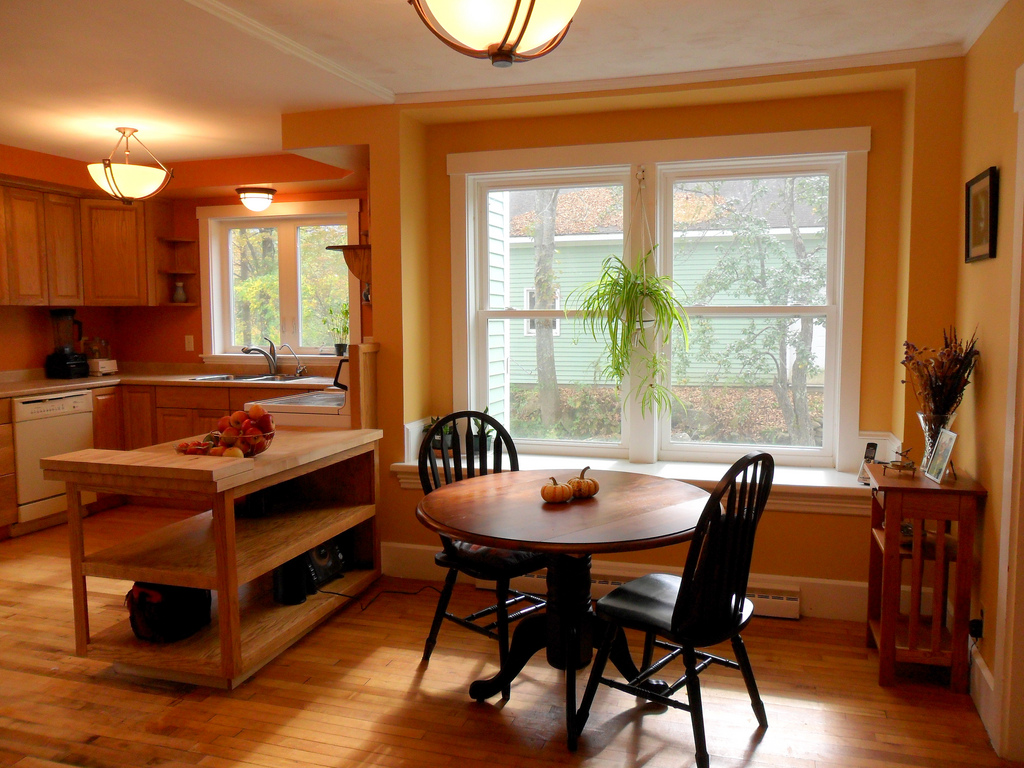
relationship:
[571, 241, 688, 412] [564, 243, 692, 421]
leaves on leaves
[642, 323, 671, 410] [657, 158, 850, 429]
leaves on tree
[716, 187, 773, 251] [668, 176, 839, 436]
leaves on tree